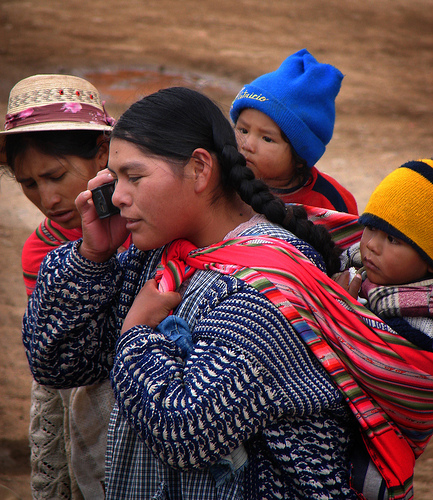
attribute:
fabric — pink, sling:
[150, 236, 431, 496]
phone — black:
[93, 181, 118, 228]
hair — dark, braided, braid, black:
[110, 81, 345, 275]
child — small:
[225, 50, 365, 269]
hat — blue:
[229, 50, 344, 163]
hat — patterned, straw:
[2, 67, 111, 145]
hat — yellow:
[353, 156, 432, 267]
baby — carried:
[326, 160, 432, 461]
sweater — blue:
[21, 219, 371, 498]